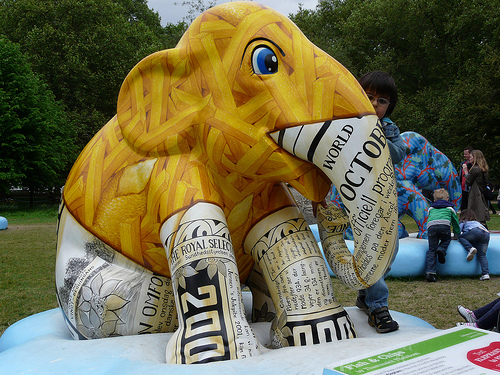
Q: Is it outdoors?
A: Yes, it is outdoors.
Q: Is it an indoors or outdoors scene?
A: It is outdoors.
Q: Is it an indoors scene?
A: No, it is outdoors.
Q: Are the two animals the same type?
A: Yes, all the animals are elephants.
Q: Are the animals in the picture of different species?
A: No, all the animals are elephants.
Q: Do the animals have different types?
A: No, all the animals are elephants.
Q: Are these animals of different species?
A: No, all the animals are elephants.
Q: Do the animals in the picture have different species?
A: No, all the animals are elephants.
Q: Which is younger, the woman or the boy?
A: The boy is younger than the woman.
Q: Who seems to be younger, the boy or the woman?
A: The boy is younger than the woman.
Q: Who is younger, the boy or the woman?
A: The boy is younger than the woman.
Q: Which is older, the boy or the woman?
A: The woman is older than the boy.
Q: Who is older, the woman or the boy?
A: The woman is older than the boy.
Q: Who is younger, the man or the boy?
A: The boy is younger than the man.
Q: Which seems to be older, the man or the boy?
A: The man is older than the boy.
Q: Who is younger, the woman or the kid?
A: The kid is younger than the woman.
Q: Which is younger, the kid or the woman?
A: The kid is younger than the woman.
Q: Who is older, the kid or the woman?
A: The woman is older than the kid.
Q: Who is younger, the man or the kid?
A: The kid is younger than the man.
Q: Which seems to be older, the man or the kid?
A: The man is older than the kid.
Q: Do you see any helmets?
A: No, there are no helmets.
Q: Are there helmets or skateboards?
A: No, there are no helmets or skateboards.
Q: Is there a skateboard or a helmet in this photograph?
A: No, there are no helmets or skateboards.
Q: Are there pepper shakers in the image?
A: No, there are no pepper shakers.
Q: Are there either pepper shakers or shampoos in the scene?
A: No, there are no pepper shakers or shampoos.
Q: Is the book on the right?
A: Yes, the book is on the right of the image.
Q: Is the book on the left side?
A: No, the book is on the right of the image.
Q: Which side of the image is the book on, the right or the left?
A: The book is on the right of the image.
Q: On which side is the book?
A: The book is on the right of the image.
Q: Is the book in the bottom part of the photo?
A: Yes, the book is in the bottom of the image.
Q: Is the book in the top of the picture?
A: No, the book is in the bottom of the image.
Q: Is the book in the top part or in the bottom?
A: The book is in the bottom of the image.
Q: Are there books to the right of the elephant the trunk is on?
A: Yes, there is a book to the right of the elephant.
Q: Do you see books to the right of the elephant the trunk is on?
A: Yes, there is a book to the right of the elephant.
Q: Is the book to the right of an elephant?
A: Yes, the book is to the right of an elephant.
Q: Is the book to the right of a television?
A: No, the book is to the right of an elephant.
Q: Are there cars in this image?
A: No, there are no cars.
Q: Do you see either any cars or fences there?
A: No, there are no cars or fences.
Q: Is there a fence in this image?
A: No, there are no fences.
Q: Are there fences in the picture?
A: No, there are no fences.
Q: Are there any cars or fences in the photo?
A: No, there are no fences or cars.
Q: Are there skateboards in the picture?
A: No, there are no skateboards.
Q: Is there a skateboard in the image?
A: No, there are no skateboards.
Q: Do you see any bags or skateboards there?
A: No, there are no skateboards or bags.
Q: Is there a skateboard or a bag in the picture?
A: No, there are no skateboards or bags.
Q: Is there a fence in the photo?
A: No, there are no fences.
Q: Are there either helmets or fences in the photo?
A: No, there are no fences or helmets.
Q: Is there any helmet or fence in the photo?
A: No, there are no fences or helmets.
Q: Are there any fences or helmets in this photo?
A: No, there are no fences or helmets.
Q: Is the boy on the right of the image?
A: Yes, the boy is on the right of the image.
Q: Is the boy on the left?
A: No, the boy is on the right of the image.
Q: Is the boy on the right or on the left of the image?
A: The boy is on the right of the image.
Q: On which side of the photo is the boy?
A: The boy is on the right of the image.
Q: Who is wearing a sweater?
A: The boy is wearing a sweater.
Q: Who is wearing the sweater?
A: The boy is wearing a sweater.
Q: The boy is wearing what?
A: The boy is wearing a sweater.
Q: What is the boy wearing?
A: The boy is wearing a sweater.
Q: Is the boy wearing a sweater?
A: Yes, the boy is wearing a sweater.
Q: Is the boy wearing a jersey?
A: No, the boy is wearing a sweater.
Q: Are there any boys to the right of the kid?
A: Yes, there is a boy to the right of the kid.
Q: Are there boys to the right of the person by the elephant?
A: Yes, there is a boy to the right of the kid.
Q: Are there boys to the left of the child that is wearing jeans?
A: No, the boy is to the right of the kid.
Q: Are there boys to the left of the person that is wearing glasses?
A: No, the boy is to the right of the kid.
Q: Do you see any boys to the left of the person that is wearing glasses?
A: No, the boy is to the right of the kid.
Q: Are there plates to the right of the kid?
A: No, there is a boy to the right of the kid.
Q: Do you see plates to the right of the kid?
A: No, there is a boy to the right of the kid.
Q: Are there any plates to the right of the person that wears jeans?
A: No, there is a boy to the right of the kid.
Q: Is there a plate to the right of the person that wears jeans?
A: No, there is a boy to the right of the kid.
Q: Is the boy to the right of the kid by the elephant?
A: Yes, the boy is to the right of the kid.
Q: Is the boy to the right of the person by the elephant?
A: Yes, the boy is to the right of the kid.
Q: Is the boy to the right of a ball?
A: No, the boy is to the right of the kid.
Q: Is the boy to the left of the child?
A: No, the boy is to the right of the child.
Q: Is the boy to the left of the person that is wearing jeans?
A: No, the boy is to the right of the child.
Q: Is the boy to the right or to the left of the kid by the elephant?
A: The boy is to the right of the kid.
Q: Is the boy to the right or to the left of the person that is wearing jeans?
A: The boy is to the right of the kid.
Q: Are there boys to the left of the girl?
A: Yes, there is a boy to the left of the girl.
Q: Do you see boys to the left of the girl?
A: Yes, there is a boy to the left of the girl.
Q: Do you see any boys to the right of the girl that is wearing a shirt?
A: No, the boy is to the left of the girl.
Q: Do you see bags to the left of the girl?
A: No, there is a boy to the left of the girl.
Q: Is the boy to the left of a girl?
A: Yes, the boy is to the left of a girl.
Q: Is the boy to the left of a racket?
A: No, the boy is to the left of a girl.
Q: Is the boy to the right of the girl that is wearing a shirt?
A: No, the boy is to the left of the girl.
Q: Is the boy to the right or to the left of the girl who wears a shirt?
A: The boy is to the left of the girl.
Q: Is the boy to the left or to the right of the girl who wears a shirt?
A: The boy is to the left of the girl.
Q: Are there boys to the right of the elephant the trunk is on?
A: Yes, there is a boy to the right of the elephant.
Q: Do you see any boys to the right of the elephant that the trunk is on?
A: Yes, there is a boy to the right of the elephant.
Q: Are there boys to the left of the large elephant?
A: No, the boy is to the right of the elephant.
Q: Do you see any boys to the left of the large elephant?
A: No, the boy is to the right of the elephant.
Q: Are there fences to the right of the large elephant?
A: No, there is a boy to the right of the elephant.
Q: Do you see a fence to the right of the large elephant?
A: No, there is a boy to the right of the elephant.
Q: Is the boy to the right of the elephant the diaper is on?
A: Yes, the boy is to the right of the elephant.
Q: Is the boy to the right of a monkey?
A: No, the boy is to the right of the elephant.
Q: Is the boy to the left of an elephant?
A: No, the boy is to the right of an elephant.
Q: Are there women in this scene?
A: Yes, there is a woman.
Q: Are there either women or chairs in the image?
A: Yes, there is a woman.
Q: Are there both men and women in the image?
A: Yes, there are both a woman and a man.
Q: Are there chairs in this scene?
A: No, there are no chairs.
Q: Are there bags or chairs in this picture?
A: No, there are no chairs or bags.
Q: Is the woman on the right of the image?
A: Yes, the woman is on the right of the image.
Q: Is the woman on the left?
A: No, the woman is on the right of the image.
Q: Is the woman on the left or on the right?
A: The woman is on the right of the image.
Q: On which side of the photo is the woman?
A: The woman is on the right of the image.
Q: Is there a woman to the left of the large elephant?
A: No, the woman is to the right of the elephant.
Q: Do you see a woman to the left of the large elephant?
A: No, the woman is to the right of the elephant.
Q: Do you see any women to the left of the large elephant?
A: No, the woman is to the right of the elephant.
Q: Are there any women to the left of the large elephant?
A: No, the woman is to the right of the elephant.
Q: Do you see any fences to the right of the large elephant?
A: No, there is a woman to the right of the elephant.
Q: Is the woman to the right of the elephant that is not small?
A: Yes, the woman is to the right of the elephant.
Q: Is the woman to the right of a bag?
A: No, the woman is to the right of the elephant.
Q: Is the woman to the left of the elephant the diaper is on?
A: No, the woman is to the right of the elephant.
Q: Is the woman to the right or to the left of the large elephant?
A: The woman is to the right of the elephant.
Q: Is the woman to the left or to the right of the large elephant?
A: The woman is to the right of the elephant.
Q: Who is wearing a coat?
A: The woman is wearing a coat.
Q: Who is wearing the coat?
A: The woman is wearing a coat.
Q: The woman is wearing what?
A: The woman is wearing a coat.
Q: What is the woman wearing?
A: The woman is wearing a coat.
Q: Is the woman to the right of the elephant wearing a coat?
A: Yes, the woman is wearing a coat.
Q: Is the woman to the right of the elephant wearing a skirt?
A: No, the woman is wearing a coat.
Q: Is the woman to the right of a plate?
A: No, the woman is to the right of the elephant.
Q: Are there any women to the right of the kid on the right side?
A: Yes, there is a woman to the right of the child.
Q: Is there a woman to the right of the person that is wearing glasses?
A: Yes, there is a woman to the right of the child.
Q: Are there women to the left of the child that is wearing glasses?
A: No, the woman is to the right of the child.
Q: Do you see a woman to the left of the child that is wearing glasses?
A: No, the woman is to the right of the child.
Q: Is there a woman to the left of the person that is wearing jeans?
A: No, the woman is to the right of the child.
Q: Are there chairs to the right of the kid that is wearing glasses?
A: No, there is a woman to the right of the kid.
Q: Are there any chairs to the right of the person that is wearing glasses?
A: No, there is a woman to the right of the kid.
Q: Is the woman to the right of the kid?
A: Yes, the woman is to the right of the kid.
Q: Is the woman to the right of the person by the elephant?
A: Yes, the woman is to the right of the kid.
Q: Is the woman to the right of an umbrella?
A: No, the woman is to the right of the kid.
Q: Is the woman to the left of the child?
A: No, the woman is to the right of the child.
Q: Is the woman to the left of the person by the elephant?
A: No, the woman is to the right of the child.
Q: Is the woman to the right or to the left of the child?
A: The woman is to the right of the child.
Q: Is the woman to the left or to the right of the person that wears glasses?
A: The woman is to the right of the child.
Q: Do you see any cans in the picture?
A: No, there are no cans.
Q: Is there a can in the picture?
A: No, there are no cans.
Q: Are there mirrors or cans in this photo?
A: No, there are no cans or mirrors.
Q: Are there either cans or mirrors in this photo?
A: No, there are no cans or mirrors.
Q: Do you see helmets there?
A: No, there are no helmets.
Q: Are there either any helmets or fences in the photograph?
A: No, there are no helmets or fences.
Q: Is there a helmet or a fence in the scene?
A: No, there are no helmets or fences.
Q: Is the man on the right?
A: Yes, the man is on the right of the image.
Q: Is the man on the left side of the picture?
A: No, the man is on the right of the image.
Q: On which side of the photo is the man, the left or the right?
A: The man is on the right of the image.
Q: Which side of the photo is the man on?
A: The man is on the right of the image.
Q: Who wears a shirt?
A: The man wears a shirt.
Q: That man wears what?
A: The man wears a shirt.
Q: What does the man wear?
A: The man wears a shirt.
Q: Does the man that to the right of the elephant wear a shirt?
A: Yes, the man wears a shirt.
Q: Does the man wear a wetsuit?
A: No, the man wears a shirt.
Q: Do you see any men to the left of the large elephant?
A: No, the man is to the right of the elephant.